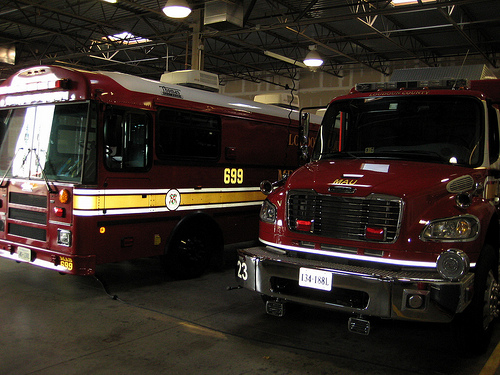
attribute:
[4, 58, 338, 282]
bus — red, gold, dark red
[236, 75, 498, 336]
fire truck — red, dark red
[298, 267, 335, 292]
license plate — black, white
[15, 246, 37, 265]
license plate — black, white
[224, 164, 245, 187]
gold number — yellow, 699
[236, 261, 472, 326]
bumper — silver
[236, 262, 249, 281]
number 23 — white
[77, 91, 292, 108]
roof — white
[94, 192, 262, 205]
lines — yellow, white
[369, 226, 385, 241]
emergency lights — red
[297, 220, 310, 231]
emergency lights — red